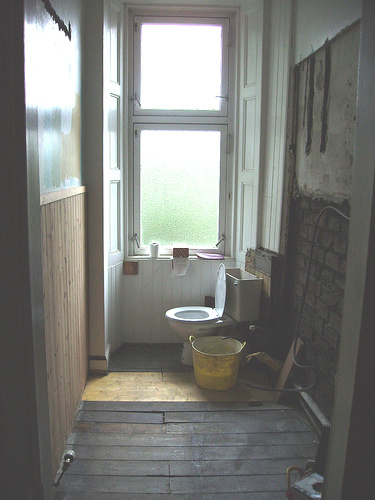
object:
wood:
[40, 186, 91, 491]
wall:
[4, 0, 89, 500]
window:
[126, 10, 231, 261]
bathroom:
[3, 0, 374, 499]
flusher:
[233, 282, 239, 286]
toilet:
[164, 262, 262, 366]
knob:
[215, 95, 227, 101]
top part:
[23, 1, 84, 198]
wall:
[277, 2, 352, 431]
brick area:
[308, 226, 335, 251]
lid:
[214, 262, 227, 316]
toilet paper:
[149, 241, 159, 260]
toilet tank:
[225, 267, 263, 324]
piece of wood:
[272, 334, 304, 402]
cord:
[246, 204, 350, 393]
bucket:
[177, 334, 254, 398]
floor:
[56, 342, 329, 500]